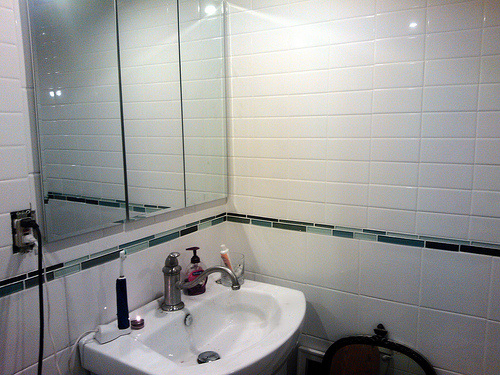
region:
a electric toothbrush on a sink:
[103, 241, 133, 348]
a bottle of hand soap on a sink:
[182, 233, 210, 295]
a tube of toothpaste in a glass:
[217, 235, 247, 283]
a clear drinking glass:
[221, 248, 251, 287]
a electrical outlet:
[11, 208, 39, 255]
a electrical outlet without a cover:
[12, 204, 39, 251]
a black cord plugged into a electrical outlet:
[17, 212, 47, 232]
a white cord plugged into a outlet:
[16, 230, 43, 255]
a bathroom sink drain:
[187, 335, 238, 368]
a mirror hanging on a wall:
[27, 32, 232, 242]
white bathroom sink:
[77, 242, 307, 372]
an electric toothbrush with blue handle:
[117, 250, 129, 327]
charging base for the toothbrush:
[92, 323, 127, 343]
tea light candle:
[129, 317, 145, 331]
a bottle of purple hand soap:
[184, 246, 209, 293]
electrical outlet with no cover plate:
[8, 208, 38, 253]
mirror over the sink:
[27, 3, 230, 235]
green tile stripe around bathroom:
[0, 205, 498, 295]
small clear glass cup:
[220, 250, 243, 285]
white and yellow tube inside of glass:
[220, 243, 233, 274]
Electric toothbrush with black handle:
[115, 250, 129, 330]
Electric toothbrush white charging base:
[92, 328, 131, 344]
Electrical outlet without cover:
[6, 206, 38, 256]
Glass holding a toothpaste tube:
[220, 242, 247, 284]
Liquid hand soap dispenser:
[185, 246, 207, 291]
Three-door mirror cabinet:
[24, 0, 230, 242]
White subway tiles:
[227, 0, 497, 215]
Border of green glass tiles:
[225, 211, 497, 258]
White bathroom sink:
[80, 267, 307, 373]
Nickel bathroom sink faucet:
[161, 253, 241, 310]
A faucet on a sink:
[160, 252, 238, 306]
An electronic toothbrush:
[112, 248, 132, 337]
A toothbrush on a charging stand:
[20, 235, 132, 373]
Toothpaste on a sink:
[215, 243, 237, 285]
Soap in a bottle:
[182, 245, 209, 289]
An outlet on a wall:
[8, 210, 40, 260]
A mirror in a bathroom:
[17, 0, 227, 243]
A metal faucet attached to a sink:
[159, 250, 239, 315]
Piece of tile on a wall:
[368, 182, 418, 210]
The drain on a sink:
[195, 347, 220, 364]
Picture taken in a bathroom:
[7, 5, 487, 365]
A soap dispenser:
[182, 231, 211, 284]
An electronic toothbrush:
[86, 251, 139, 343]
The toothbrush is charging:
[15, 215, 135, 364]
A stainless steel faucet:
[155, 253, 241, 310]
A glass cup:
[212, 236, 249, 283]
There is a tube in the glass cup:
[219, 231, 243, 275]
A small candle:
[128, 316, 146, 330]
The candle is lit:
[125, 309, 156, 333]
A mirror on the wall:
[20, 6, 251, 248]